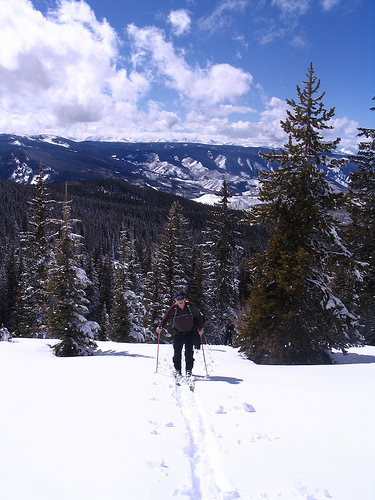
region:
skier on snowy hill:
[142, 285, 215, 393]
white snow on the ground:
[23, 398, 52, 423]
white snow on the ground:
[148, 434, 194, 473]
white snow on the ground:
[246, 404, 304, 452]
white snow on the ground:
[286, 411, 352, 456]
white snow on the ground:
[60, 466, 118, 494]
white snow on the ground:
[135, 415, 189, 460]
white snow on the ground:
[78, 402, 147, 440]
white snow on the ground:
[210, 410, 296, 456]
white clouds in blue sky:
[78, 67, 132, 111]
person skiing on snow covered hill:
[143, 282, 243, 392]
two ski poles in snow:
[149, 325, 218, 382]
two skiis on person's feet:
[167, 367, 202, 395]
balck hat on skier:
[168, 287, 189, 303]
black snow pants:
[168, 330, 198, 371]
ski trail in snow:
[162, 387, 238, 498]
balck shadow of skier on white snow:
[188, 363, 245, 394]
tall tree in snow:
[234, 60, 360, 377]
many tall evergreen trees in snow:
[2, 149, 371, 367]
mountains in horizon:
[1, 122, 374, 209]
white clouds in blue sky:
[24, 16, 108, 89]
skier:
[156, 277, 201, 384]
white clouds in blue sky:
[115, 44, 148, 82]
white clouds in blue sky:
[61, 28, 99, 68]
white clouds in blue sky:
[215, 55, 247, 97]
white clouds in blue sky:
[17, 65, 69, 94]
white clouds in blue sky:
[224, 37, 266, 93]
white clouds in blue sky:
[89, 36, 135, 84]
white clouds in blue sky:
[145, 85, 210, 137]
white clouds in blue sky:
[155, 21, 203, 89]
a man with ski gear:
[151, 290, 214, 390]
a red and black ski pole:
[150, 327, 163, 378]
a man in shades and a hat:
[174, 291, 189, 308]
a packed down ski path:
[172, 388, 229, 498]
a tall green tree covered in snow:
[242, 79, 352, 355]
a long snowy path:
[0, 377, 371, 497]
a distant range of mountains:
[1, 130, 364, 207]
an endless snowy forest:
[7, 189, 209, 327]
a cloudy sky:
[0, 0, 148, 125]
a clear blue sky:
[212, 1, 372, 92]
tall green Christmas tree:
[247, 59, 347, 369]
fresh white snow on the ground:
[21, 366, 109, 423]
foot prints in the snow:
[232, 428, 290, 450]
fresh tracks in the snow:
[165, 370, 214, 492]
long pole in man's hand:
[145, 321, 164, 375]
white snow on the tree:
[70, 260, 92, 330]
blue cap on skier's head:
[157, 284, 194, 303]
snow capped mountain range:
[173, 158, 249, 205]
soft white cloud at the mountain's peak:
[103, 116, 169, 149]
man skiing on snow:
[144, 281, 227, 408]